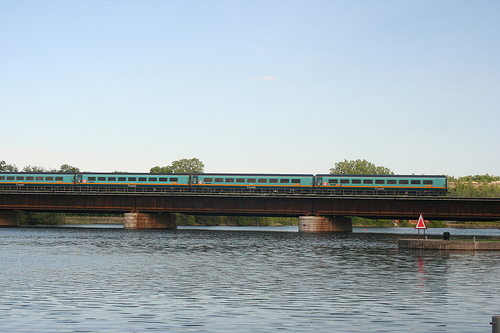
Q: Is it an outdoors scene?
A: Yes, it is outdoors.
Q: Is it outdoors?
A: Yes, it is outdoors.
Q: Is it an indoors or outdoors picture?
A: It is outdoors.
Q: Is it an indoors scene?
A: No, it is outdoors.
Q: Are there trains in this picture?
A: Yes, there is a train.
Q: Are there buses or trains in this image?
A: Yes, there is a train.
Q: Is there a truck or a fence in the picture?
A: No, there are no fences or trucks.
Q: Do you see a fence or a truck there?
A: No, there are no fences or trucks.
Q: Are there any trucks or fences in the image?
A: No, there are no fences or trucks.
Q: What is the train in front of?
A: The train is in front of the trees.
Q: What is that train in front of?
A: The train is in front of the trees.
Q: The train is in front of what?
A: The train is in front of the trees.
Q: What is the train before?
A: The train is in front of the trees.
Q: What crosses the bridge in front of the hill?
A: The train crosses the bridge.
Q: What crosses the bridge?
A: The train crosses the bridge.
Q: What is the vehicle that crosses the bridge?
A: The vehicle is a train.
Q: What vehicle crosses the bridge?
A: The vehicle is a train.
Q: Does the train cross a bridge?
A: Yes, the train crosses a bridge.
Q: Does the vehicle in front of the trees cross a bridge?
A: Yes, the train crosses a bridge.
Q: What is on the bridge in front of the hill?
A: The train is on the bridge.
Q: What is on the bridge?
A: The train is on the bridge.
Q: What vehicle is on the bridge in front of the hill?
A: The vehicle is a train.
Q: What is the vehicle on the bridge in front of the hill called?
A: The vehicle is a train.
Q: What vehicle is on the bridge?
A: The vehicle is a train.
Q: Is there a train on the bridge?
A: Yes, there is a train on the bridge.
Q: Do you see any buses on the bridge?
A: No, there is a train on the bridge.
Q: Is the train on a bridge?
A: Yes, the train is on a bridge.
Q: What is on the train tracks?
A: The train is on the tracks.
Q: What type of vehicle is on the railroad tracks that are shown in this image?
A: The vehicle is a train.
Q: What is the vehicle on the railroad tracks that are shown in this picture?
A: The vehicle is a train.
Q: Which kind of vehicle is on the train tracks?
A: The vehicle is a train.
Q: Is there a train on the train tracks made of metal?
A: Yes, there is a train on the railroad tracks.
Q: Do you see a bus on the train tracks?
A: No, there is a train on the train tracks.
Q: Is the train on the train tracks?
A: Yes, the train is on the train tracks.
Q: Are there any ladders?
A: No, there are no ladders.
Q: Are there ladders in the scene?
A: No, there are no ladders.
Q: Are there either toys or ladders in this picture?
A: No, there are no ladders or toys.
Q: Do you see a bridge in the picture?
A: Yes, there is a bridge.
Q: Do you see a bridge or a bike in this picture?
A: Yes, there is a bridge.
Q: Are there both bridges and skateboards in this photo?
A: No, there is a bridge but no skateboards.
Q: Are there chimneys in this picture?
A: No, there are no chimneys.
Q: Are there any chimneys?
A: No, there are no chimneys.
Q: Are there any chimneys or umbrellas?
A: No, there are no chimneys or umbrellas.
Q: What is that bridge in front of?
A: The bridge is in front of the hill.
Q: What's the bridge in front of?
A: The bridge is in front of the hill.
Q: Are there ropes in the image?
A: No, there are no ropes.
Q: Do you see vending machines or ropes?
A: No, there are no ropes or vending machines.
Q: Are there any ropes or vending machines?
A: No, there are no ropes or vending machines.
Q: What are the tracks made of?
A: The tracks are made of metal.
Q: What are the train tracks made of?
A: The tracks are made of metal.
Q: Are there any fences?
A: No, there are no fences.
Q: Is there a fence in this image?
A: No, there are no fences.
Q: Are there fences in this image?
A: No, there are no fences.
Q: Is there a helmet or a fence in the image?
A: No, there are no fences or helmets.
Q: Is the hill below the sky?
A: Yes, the hill is below the sky.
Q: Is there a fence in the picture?
A: No, there are no fences.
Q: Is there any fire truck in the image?
A: No, there are no fire trucks.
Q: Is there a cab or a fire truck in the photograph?
A: No, there are no fire trucks or taxis.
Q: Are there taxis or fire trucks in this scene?
A: No, there are no fire trucks or taxis.